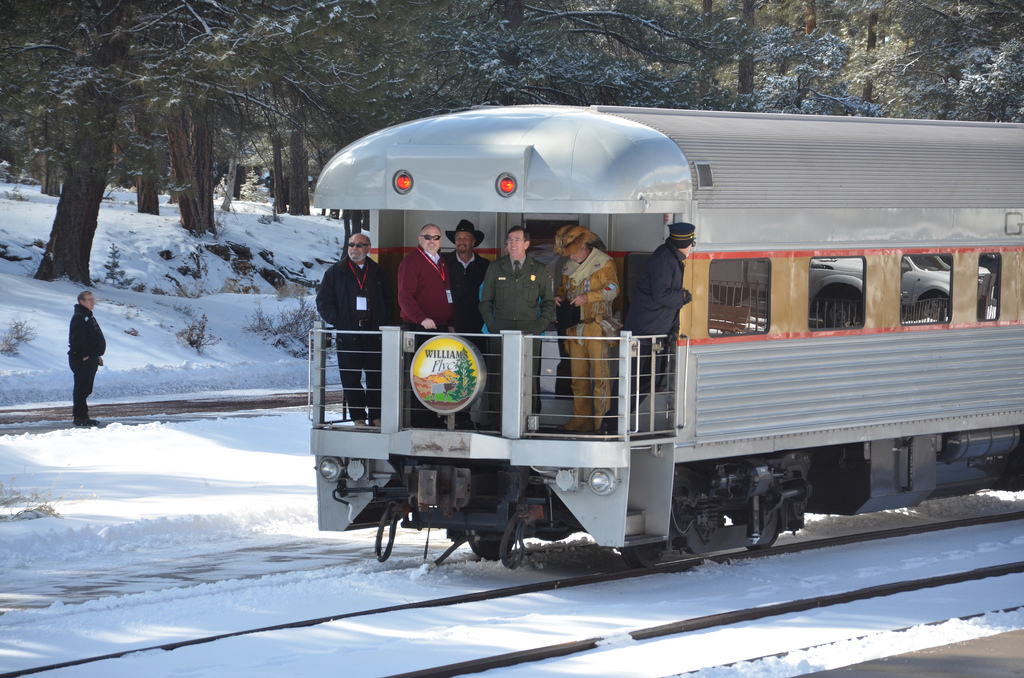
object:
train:
[307, 103, 1022, 569]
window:
[810, 255, 868, 331]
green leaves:
[28, 67, 175, 142]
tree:
[0, 2, 266, 286]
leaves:
[99, 79, 182, 178]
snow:
[0, 413, 337, 674]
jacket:
[477, 255, 556, 334]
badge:
[477, 226, 556, 431]